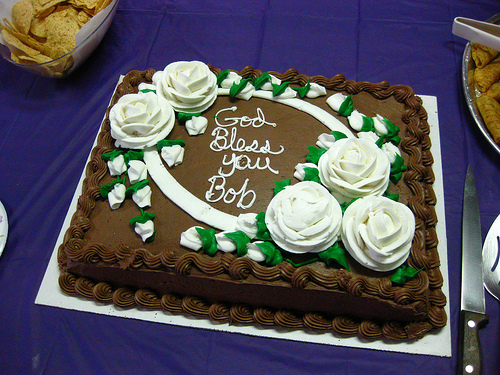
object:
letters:
[205, 175, 227, 205]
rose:
[264, 180, 339, 254]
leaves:
[222, 229, 251, 255]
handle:
[457, 309, 488, 369]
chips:
[58, 0, 104, 20]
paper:
[8, 5, 108, 62]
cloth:
[3, 2, 495, 372]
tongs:
[454, 45, 481, 70]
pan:
[456, 14, 499, 160]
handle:
[450, 15, 497, 51]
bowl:
[4, 3, 115, 75]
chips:
[2, 4, 55, 34]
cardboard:
[36, 68, 450, 358]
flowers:
[318, 136, 394, 204]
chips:
[46, 12, 81, 55]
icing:
[54, 62, 451, 347]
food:
[455, 15, 498, 144]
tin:
[459, 25, 497, 162]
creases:
[252, 1, 273, 68]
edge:
[1, 193, 20, 267]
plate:
[0, 196, 12, 268]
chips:
[7, 31, 38, 59]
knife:
[450, 155, 492, 373]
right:
[334, 29, 487, 372]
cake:
[47, 57, 445, 346]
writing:
[202, 104, 284, 211]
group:
[270, 134, 417, 271]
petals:
[298, 216, 338, 237]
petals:
[120, 119, 159, 136]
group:
[108, 54, 225, 147]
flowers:
[337, 194, 419, 275]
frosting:
[262, 133, 428, 278]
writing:
[201, 101, 288, 222]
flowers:
[264, 177, 343, 257]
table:
[1, 3, 489, 373]